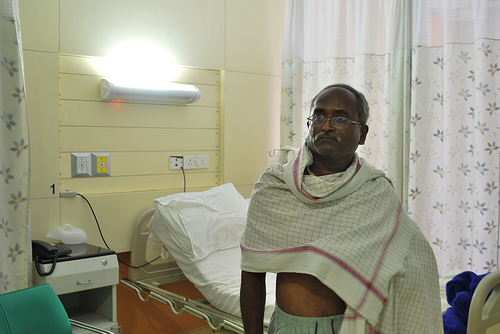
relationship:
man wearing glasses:
[241, 83, 437, 332] [301, 107, 355, 129]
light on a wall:
[82, 50, 207, 105] [30, 89, 280, 143]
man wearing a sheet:
[241, 83, 437, 332] [237, 146, 445, 334]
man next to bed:
[236, 79, 444, 334] [117, 181, 453, 334]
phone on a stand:
[31, 238, 75, 278] [33, 258, 135, 331]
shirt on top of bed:
[431, 259, 496, 329] [158, 197, 498, 316]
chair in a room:
[0, 282, 72, 332] [0, 0, 480, 331]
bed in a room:
[151, 186, 248, 306] [0, 0, 480, 331]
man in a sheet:
[241, 83, 437, 332] [237, 146, 445, 334]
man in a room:
[236, 79, 444, 334] [0, 0, 480, 331]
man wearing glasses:
[241, 83, 437, 332] [307, 112, 362, 128]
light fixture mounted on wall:
[100, 75, 204, 103] [17, 13, 273, 203]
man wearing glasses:
[236, 79, 444, 334] [306, 107, 361, 130]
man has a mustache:
[236, 79, 444, 334] [301, 130, 365, 161]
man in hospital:
[241, 83, 437, 332] [1, 0, 484, 330]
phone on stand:
[20, 227, 71, 269] [33, 240, 124, 334]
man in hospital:
[236, 79, 444, 334] [1, 0, 484, 330]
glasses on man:
[303, 109, 375, 142] [237, 80, 394, 332]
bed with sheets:
[117, 181, 453, 334] [180, 207, 220, 270]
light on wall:
[89, 39, 203, 104] [108, 110, 173, 199]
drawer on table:
[44, 253, 126, 300] [29, 228, 125, 332]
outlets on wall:
[165, 148, 214, 178] [107, 120, 176, 197]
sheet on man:
[246, 150, 442, 332] [237, 80, 394, 332]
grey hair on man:
[309, 81, 371, 115] [238, 65, 442, 332]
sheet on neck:
[237, 146, 445, 334] [302, 151, 356, 190]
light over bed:
[89, 39, 203, 104] [131, 192, 272, 313]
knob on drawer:
[71, 275, 108, 289] [43, 250, 128, 307]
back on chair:
[10, 280, 63, 330] [5, 280, 120, 332]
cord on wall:
[52, 193, 159, 247] [44, 74, 188, 221]